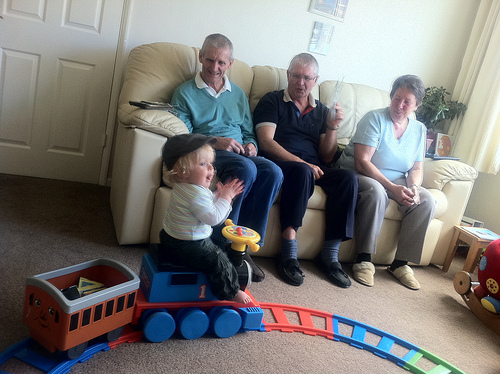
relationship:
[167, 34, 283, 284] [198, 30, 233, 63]
man has hair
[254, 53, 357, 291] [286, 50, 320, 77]
man has hair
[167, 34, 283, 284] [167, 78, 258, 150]
man wearing sweater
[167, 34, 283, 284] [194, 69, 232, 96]
man wearing shirt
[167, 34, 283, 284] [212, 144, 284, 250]
man wearing jeans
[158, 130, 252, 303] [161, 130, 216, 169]
child wearing hat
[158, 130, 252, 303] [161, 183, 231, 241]
child wearing shirt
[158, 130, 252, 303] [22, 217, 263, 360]
child sitting on top of train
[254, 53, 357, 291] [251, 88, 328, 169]
man wearing shirt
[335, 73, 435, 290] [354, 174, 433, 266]
people wearing pants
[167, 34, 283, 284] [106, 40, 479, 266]
man sitting on couch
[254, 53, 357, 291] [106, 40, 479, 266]
man sitting on couch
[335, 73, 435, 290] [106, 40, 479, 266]
people sitting on couch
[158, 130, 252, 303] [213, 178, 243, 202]
child clapping hands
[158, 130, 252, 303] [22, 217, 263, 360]
child sitting on train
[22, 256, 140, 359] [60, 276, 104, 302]
train car filled with toys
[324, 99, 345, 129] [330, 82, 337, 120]
left hand holding object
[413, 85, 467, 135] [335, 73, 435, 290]
plant next to people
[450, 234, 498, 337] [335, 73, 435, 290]
rocking toy near people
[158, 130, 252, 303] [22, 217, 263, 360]
child riding on train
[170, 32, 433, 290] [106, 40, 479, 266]
people sitting on couch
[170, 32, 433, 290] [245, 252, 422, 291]
people wearing shoes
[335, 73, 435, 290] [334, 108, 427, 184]
people wearing shirt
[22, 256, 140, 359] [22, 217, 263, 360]
train car attached to train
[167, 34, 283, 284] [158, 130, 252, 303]
man looking at child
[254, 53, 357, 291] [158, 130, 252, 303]
man looking at child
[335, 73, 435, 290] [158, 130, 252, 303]
people looking at child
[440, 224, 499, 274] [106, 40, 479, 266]
table next to couch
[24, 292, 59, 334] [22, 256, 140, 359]
face on side of train car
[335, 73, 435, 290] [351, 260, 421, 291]
people wearing slippers